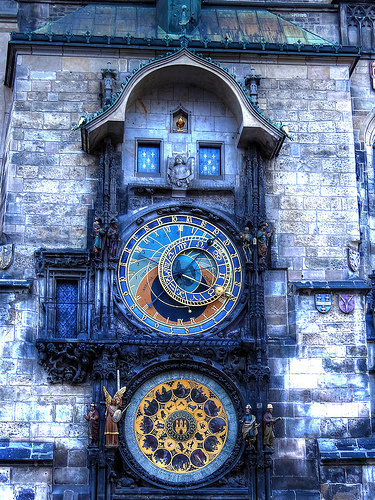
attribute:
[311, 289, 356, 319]
couple — medieval looking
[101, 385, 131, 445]
figurine — copper, angel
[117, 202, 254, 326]
clock — very cool looking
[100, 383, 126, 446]
statue — small, winged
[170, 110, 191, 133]
statuette — gold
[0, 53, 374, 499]
wall — exterior, brick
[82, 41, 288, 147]
arch — patina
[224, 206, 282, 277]
statue — small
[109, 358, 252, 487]
clock — odd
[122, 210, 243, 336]
clock — astronomical, ornate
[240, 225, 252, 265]
art figure — different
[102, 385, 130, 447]
statues — religious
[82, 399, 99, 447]
statues — religious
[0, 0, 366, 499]
wall — exterior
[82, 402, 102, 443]
man — figure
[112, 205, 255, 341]
clock — odd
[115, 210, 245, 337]
calendar — mechanical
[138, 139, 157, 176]
window — pretty, stained glass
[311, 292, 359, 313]
crests — couple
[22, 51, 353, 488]
wall — exterior